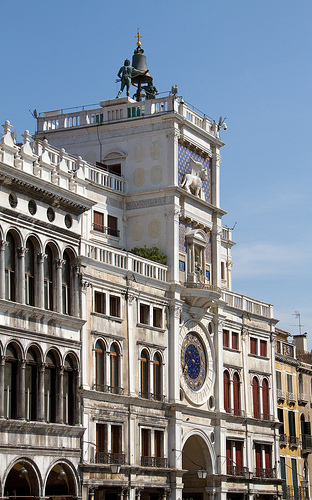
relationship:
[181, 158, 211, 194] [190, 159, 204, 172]
animal has wings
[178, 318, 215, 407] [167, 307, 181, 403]
round terrace near columns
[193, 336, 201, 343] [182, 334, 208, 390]
gold figures in a circle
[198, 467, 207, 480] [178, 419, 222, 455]
lantern hanging over archway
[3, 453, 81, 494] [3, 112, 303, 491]
arches on building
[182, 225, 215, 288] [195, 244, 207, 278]
terrace with a door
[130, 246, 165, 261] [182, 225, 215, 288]
tree on terrace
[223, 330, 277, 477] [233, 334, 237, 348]
windows in red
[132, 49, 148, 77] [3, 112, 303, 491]
bell on building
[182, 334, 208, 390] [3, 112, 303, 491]
circle design on building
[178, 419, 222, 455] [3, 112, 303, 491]
archway on building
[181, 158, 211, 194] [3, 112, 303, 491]
animal with wings on building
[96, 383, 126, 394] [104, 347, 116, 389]
balcony has pillars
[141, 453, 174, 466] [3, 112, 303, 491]
railing on building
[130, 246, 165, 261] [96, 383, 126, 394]
tree on a balcony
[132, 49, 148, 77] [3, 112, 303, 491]
bell on top of building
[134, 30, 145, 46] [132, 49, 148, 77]
cross over bell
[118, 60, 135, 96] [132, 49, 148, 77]
statue on bell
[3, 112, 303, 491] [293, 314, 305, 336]
building with an antenna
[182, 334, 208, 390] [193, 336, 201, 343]
circle has gold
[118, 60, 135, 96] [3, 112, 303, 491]
statue on building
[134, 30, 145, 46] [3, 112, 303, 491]
cross on building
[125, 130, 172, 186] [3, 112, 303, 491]
wall on building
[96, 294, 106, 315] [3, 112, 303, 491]
window on building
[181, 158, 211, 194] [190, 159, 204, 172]
horse has wings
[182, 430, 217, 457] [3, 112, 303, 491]
arch on building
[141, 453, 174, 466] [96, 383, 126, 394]
railing on balcony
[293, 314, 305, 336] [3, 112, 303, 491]
antenna on building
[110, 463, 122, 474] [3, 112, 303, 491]
light in front of building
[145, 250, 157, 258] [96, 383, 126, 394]
green tree on balcony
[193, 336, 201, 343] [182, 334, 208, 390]
gold on circle